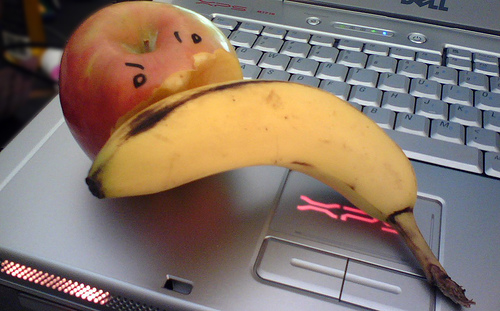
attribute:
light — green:
[370, 26, 378, 35]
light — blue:
[379, 29, 389, 37]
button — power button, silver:
[406, 30, 429, 46]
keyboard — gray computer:
[208, 11, 498, 181]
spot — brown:
[228, 96, 238, 105]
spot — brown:
[263, 126, 271, 134]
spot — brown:
[280, 113, 290, 123]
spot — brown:
[328, 108, 338, 117]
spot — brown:
[289, 157, 319, 169]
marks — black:
[124, 29, 202, 87]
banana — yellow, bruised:
[55, 74, 483, 293]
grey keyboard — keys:
[204, 12, 499, 165]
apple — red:
[58, 3, 258, 148]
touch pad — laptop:
[266, 165, 462, 308]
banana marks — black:
[115, 71, 303, 129]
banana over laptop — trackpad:
[72, 76, 476, 298]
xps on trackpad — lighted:
[296, 184, 411, 239]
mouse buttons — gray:
[249, 235, 450, 310]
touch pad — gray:
[257, 164, 449, 309]